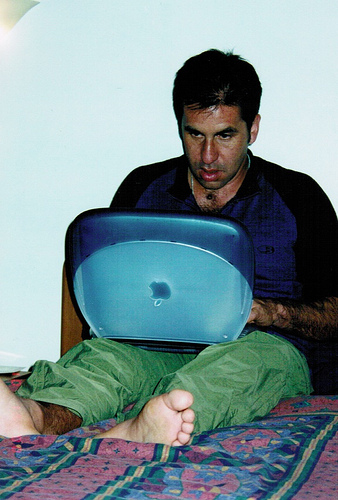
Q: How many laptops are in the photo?
A: One.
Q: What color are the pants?
A: Green.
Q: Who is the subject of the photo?
A: The man.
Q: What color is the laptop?
A: Blue.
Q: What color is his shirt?
A: Black.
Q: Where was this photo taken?
A: A bedroom.